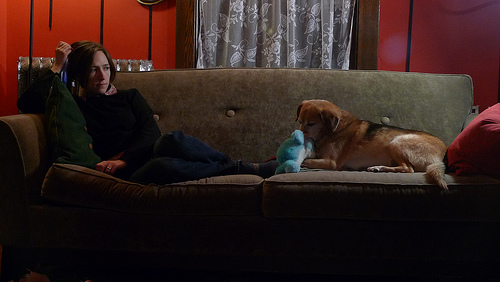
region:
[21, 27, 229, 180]
Woman sitting on a couch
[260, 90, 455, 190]
Dog laying on a couch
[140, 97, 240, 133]
Buttons on the back of a couch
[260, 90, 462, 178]
Dog with a blue toy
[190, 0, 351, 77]
White lace curtains on a window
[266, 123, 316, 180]
Blue and white stuffed animal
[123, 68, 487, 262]
Green couch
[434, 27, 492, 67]
Red walls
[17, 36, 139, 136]
Woman with right hand propped on her head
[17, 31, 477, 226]
Woman and a dog sitting on the sofa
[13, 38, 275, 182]
Woman lying on sofa.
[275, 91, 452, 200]
Brown dog lying on sofa with blue and white toy.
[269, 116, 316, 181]
Blue and white stuffed animal toy.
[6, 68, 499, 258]
Brown sofa holding woman and dog.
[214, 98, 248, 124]
Button on back of sofa.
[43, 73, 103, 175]
Green pillow on sofa.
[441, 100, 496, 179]
Red pillow on sofa.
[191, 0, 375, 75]
Sheer curtains with white flowers hanging over window.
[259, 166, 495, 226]
Edge of brown sofa cushion.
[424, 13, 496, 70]
Orange wall behind brown sofa.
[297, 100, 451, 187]
a tan and black dog on a couch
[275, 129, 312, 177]
a bright blue and white stuffed animal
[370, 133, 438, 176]
the brown leg of a dog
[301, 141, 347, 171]
the brown leg of a dog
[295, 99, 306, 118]
the brown ear of a dog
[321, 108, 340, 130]
the brown ear of a dog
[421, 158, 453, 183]
the brown tail of a dog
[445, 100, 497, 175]
a large red pillow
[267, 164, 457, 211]
a olive green cushion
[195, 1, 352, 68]
a white lace curtain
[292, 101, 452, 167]
the dog is brown and black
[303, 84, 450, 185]
the dog is on the couch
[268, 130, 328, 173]
the teddybear is grenn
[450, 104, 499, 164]
the pillow is red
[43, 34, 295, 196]
the woman is leaning on the couch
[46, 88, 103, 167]
the pillow is green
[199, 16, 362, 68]
the curatain is white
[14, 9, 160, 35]
the wall is red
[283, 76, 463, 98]
the couch is brown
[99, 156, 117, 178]
a ring is on her finger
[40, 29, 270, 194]
A lady on the couch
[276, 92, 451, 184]
A dog on the couch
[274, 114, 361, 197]
A stuffed animal in the dogs mouth.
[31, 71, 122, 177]
A green pillow on the couch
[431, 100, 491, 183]
A red pillow on the couch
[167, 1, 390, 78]
Gray and flowered curtains.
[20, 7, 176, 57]
Red walls with black stripes.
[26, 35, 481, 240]
A grey couch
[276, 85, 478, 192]
The dog is tan with dark spots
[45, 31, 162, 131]
The lady is looking at the dog.